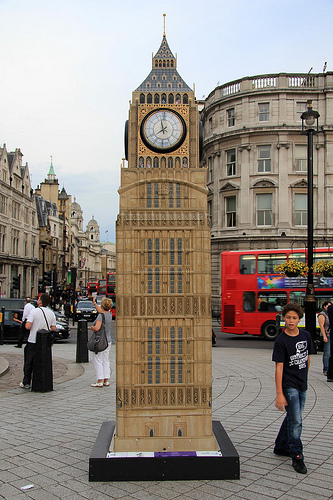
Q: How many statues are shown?
A: One.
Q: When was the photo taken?
A: Daytime.